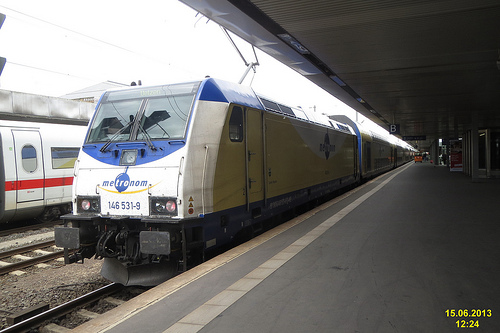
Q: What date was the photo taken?
A: 06.15.2013.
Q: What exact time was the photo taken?
A: 12:24.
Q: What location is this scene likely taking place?
A: Trains station.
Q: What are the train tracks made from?
A: Steel.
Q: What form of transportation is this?
A: A commuter train.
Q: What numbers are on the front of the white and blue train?
A: 146 531-9.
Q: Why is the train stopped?
A: To pick up passengers.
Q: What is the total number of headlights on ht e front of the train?
A: 4.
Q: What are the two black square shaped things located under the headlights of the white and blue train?
A: Bumper.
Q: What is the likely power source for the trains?
A: Electricity.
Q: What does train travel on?
A: Tracks.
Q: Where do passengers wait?
A: Platform.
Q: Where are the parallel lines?
A: On the ground.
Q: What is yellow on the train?
A: The side.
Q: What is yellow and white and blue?
A: A train.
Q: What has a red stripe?
A: A train.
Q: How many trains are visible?
A: Two.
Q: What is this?
A: A train platform with trains.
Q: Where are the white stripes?
A: On the platform.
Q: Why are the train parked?
A: They are waiting for passengers to embark.